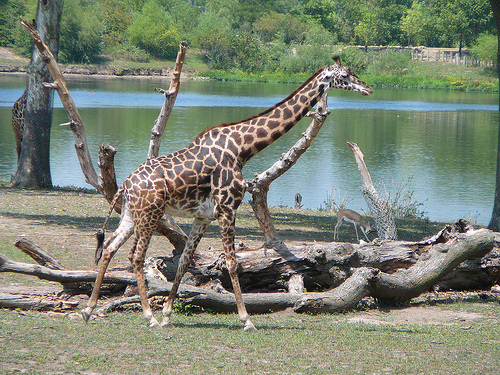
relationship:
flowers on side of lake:
[289, 49, 434, 91] [108, 85, 475, 210]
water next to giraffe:
[0, 72, 499, 227] [76, 48, 379, 331]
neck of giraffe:
[230, 82, 340, 148] [76, 48, 379, 331]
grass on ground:
[7, 187, 498, 372] [3, 182, 498, 367]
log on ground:
[12, 235, 499, 313] [3, 182, 498, 367]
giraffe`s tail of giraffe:
[93, 185, 123, 264] [76, 48, 379, 331]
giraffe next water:
[76, 48, 379, 331] [337, 98, 491, 140]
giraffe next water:
[11, 15, 36, 162] [337, 98, 491, 140]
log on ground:
[0, 216, 499, 313] [15, 211, 453, 351]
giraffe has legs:
[79, 54, 375, 332] [88, 216, 257, 335]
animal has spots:
[66, 55, 381, 346] [178, 158, 222, 189]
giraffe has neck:
[76, 48, 379, 331] [206, 87, 323, 154]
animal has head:
[66, 55, 381, 346] [320, 51, 375, 96]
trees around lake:
[315, 0, 475, 45] [3, 41, 493, 218]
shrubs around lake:
[122, 15, 320, 69] [3, 41, 493, 218]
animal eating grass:
[333, 209, 378, 244] [7, 187, 498, 372]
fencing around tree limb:
[364, 186, 396, 242] [348, 139, 388, 242]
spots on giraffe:
[166, 148, 234, 206] [64, 41, 384, 302]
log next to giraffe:
[0, 216, 499, 313] [76, 48, 379, 331]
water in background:
[0, 72, 499, 227] [0, 0, 497, 197]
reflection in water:
[368, 122, 494, 181] [274, 90, 496, 222]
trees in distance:
[178, 3, 348, 81] [194, 9, 262, 65]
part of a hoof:
[240, 314, 248, 326] [244, 323, 259, 337]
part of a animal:
[348, 209, 365, 229] [333, 209, 378, 244]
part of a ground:
[371, 328, 401, 355] [22, 320, 482, 364]